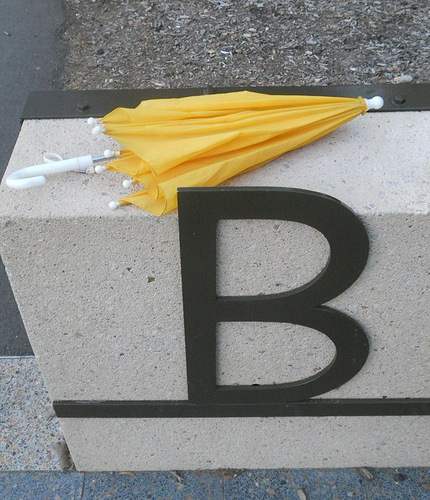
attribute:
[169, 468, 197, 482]
wood — chip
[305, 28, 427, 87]
wood — chip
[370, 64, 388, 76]
chip — wood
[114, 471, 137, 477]
wood — a chip